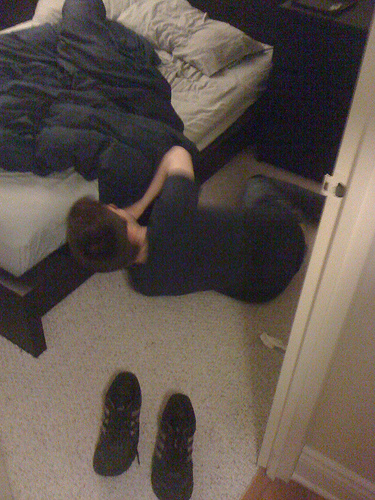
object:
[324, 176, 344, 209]
plate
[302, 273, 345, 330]
door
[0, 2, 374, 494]
doorway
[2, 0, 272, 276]
mattress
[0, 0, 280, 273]
bed covering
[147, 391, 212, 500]
shoe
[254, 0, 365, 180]
nightstand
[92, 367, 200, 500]
shoes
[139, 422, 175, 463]
stripes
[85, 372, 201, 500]
sneakers carpet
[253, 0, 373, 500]
door frame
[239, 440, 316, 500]
hallway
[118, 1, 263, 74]
white pillowcase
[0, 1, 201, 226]
blanket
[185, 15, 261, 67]
pillowcase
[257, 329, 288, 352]
elephant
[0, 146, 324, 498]
bedroom carpet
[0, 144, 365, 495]
floor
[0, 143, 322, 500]
white carpet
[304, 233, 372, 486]
wall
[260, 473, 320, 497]
wood floor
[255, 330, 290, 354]
paper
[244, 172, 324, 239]
jeans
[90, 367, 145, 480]
shoe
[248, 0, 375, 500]
door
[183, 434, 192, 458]
stripe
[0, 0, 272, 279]
bed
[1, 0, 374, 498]
bedroom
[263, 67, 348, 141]
drawer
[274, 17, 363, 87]
drawer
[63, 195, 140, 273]
hair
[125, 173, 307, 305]
shirt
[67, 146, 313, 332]
boy